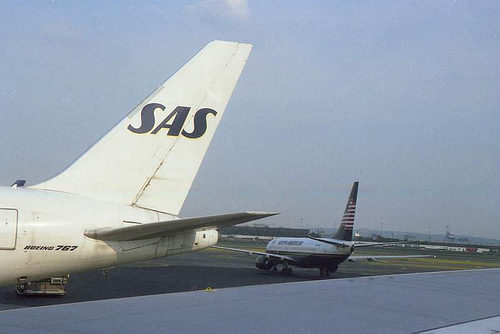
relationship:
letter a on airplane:
[152, 103, 191, 139] [0, 40, 281, 295]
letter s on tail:
[126, 99, 167, 136] [32, 39, 254, 217]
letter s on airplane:
[181, 107, 218, 139] [0, 40, 281, 295]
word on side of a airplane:
[21, 243, 54, 252] [0, 40, 281, 295]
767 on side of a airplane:
[56, 245, 78, 251] [0, 40, 281, 295]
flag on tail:
[341, 202, 356, 232] [332, 181, 365, 240]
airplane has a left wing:
[210, 181, 434, 279] [212, 245, 294, 264]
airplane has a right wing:
[210, 181, 434, 279] [350, 253, 440, 261]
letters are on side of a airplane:
[277, 239, 305, 247] [210, 181, 434, 279]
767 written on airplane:
[56, 245, 78, 251] [0, 40, 281, 295]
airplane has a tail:
[0, 40, 284, 296] [32, 39, 254, 217]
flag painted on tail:
[341, 202, 356, 232] [332, 181, 365, 240]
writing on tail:
[126, 101, 217, 142] [32, 39, 254, 217]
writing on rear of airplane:
[126, 101, 217, 142] [0, 40, 281, 295]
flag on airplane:
[341, 202, 356, 232] [210, 181, 434, 279]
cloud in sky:
[201, 1, 258, 22] [0, 1, 497, 244]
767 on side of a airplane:
[56, 245, 79, 253] [0, 40, 281, 295]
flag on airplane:
[341, 202, 356, 232] [208, 180, 361, 279]